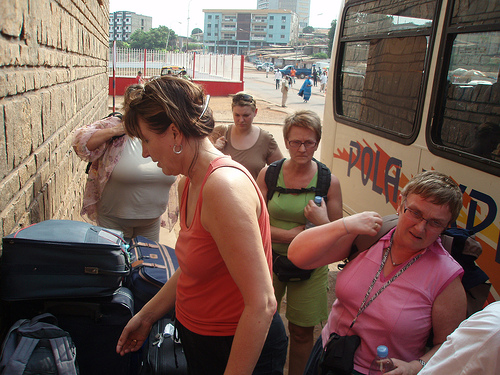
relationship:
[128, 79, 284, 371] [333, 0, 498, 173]
passengers ready to board bus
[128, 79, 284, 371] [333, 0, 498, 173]
passengers of bus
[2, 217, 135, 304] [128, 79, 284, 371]
luggauge awaits passengers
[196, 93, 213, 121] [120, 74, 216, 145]
clip secures hair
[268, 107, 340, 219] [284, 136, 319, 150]
passengers wearing eyeglasses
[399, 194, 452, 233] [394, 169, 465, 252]
sunglasses proppep top head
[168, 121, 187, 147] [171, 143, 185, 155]
ear pierced earring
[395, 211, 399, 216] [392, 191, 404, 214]
earring on ear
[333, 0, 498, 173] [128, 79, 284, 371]
bus waiting for passengers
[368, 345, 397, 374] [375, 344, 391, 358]
water bottle has lid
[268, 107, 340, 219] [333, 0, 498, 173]
passengers next to bus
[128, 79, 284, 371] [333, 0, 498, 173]
passengers next to bus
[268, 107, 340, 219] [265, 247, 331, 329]
passengers wearing shorts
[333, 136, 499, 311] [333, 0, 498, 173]
logo on bus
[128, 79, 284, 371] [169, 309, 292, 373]
passengers wearing shorts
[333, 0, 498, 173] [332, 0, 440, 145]
bus has window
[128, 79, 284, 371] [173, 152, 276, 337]
passengers wearing tank top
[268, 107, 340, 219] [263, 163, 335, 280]
passengers wearing tank top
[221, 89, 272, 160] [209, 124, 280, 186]
passengers wearing shirt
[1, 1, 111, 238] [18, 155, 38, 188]
wall made of brick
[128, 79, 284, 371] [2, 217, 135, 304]
passengers collects luggauge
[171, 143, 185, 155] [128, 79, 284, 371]
earring on passengers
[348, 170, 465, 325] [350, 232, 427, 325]
passengers has lanyard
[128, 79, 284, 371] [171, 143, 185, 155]
passengers wearing earring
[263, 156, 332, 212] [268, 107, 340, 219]
straps on passengers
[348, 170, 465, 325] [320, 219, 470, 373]
passengers wearing shirt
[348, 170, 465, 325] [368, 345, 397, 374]
passengers holding water bottle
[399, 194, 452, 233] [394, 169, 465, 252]
sunglasses on head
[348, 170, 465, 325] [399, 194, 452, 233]
passengers wearing sunglasses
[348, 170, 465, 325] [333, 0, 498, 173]
passengers ready to board bus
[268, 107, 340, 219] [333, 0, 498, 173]
passengers ready to board bus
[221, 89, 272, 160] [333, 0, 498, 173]
passengers ready to board bus